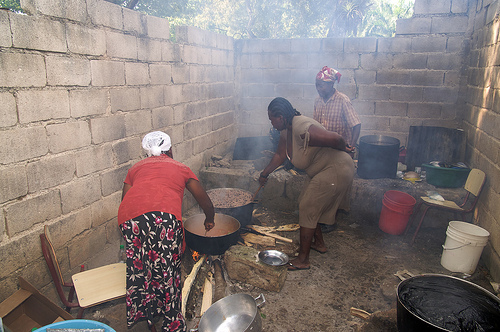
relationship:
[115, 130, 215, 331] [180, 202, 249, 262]
lady bending over pot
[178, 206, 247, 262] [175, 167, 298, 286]
pot over fire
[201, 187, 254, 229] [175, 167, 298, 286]
pot over fire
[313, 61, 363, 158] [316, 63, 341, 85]
person wearing head scarf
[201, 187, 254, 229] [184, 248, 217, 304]
pot on stove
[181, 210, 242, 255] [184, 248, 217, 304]
pot on stove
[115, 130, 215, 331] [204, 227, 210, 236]
lady holding utensil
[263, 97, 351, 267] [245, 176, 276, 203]
woman holding utensil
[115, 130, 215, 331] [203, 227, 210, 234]
lady holding utensil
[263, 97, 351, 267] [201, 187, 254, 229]
woman stirring pot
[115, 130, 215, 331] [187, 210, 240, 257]
lady stirring pot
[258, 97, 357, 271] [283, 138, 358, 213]
woman wearing brown dress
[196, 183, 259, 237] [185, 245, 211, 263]
pot over fire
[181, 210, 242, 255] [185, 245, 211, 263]
pot over fire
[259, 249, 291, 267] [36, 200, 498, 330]
plate on ground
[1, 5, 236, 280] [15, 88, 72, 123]
wall made of cement blocks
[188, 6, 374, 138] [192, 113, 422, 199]
smoke coming from wood stove